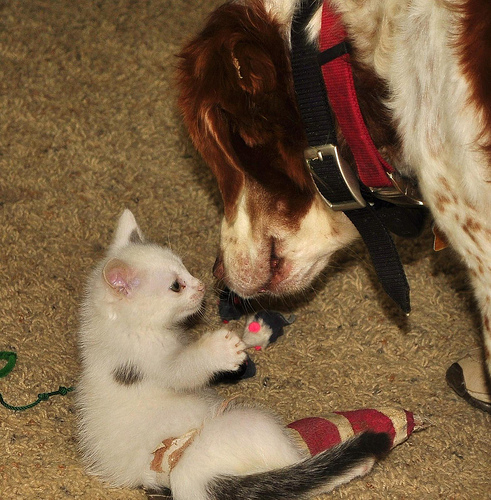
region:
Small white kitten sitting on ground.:
[85, 248, 225, 458]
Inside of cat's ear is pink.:
[111, 271, 134, 287]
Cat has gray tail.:
[238, 440, 350, 495]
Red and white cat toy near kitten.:
[289, 397, 413, 462]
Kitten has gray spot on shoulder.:
[95, 349, 166, 398]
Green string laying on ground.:
[8, 354, 59, 412]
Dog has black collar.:
[352, 205, 392, 281]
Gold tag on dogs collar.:
[419, 217, 452, 259]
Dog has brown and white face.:
[207, 166, 326, 274]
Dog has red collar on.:
[318, 76, 381, 190]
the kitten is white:
[44, 191, 356, 486]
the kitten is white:
[69, 238, 276, 449]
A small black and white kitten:
[59, 242, 387, 498]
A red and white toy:
[260, 396, 456, 487]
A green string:
[1, 349, 90, 444]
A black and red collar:
[278, 8, 456, 264]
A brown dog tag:
[416, 215, 472, 249]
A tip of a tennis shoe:
[427, 343, 489, 420]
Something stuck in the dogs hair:
[196, 39, 275, 111]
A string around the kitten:
[152, 379, 248, 484]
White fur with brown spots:
[355, 12, 488, 209]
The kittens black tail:
[201, 461, 395, 497]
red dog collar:
[318, 77, 470, 248]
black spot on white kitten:
[106, 354, 159, 394]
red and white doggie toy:
[278, 413, 429, 457]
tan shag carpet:
[333, 350, 418, 399]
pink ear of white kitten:
[96, 254, 145, 295]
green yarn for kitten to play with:
[1, 346, 71, 413]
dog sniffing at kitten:
[155, 231, 317, 326]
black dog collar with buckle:
[283, 70, 428, 322]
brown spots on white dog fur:
[427, 157, 489, 268]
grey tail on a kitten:
[205, 459, 406, 491]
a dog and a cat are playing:
[50, 0, 488, 489]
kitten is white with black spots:
[59, 204, 390, 495]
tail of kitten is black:
[199, 420, 405, 493]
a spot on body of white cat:
[100, 348, 149, 401]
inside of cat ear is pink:
[99, 252, 143, 300]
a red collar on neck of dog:
[325, 0, 426, 291]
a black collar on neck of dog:
[278, 2, 326, 147]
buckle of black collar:
[297, 139, 372, 228]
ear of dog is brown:
[186, 16, 320, 230]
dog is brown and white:
[165, 2, 489, 384]